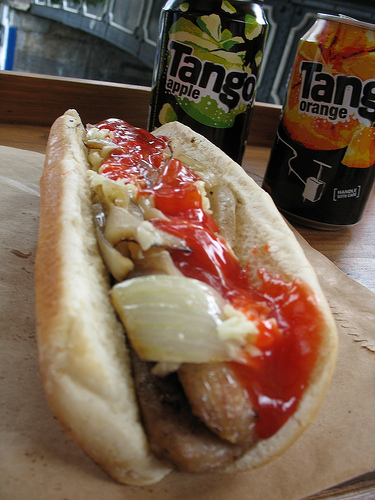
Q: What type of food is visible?
A: Hot dog.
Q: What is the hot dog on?
A: Bun.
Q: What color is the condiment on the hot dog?
A: Red.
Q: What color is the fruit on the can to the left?
A: Green.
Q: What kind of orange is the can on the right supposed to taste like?
A: Oranges.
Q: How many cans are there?
A: Two.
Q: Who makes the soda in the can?
A: Tango.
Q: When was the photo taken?
A: Daytime.